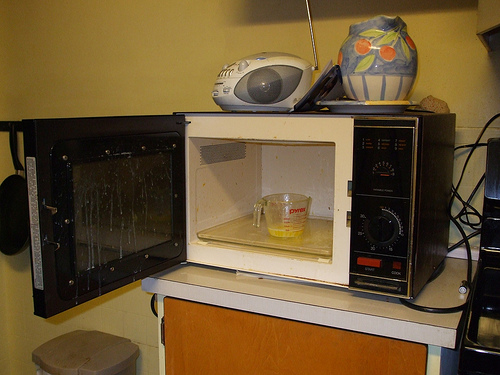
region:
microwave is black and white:
[175, 57, 413, 372]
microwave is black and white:
[57, 55, 359, 332]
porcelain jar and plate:
[336, 17, 422, 116]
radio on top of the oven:
[201, 25, 330, 112]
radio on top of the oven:
[186, 25, 353, 179]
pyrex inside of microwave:
[238, 180, 308, 235]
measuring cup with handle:
[238, 190, 308, 245]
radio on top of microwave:
[211, 45, 311, 107]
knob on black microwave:
[355, 204, 398, 264]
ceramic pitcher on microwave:
[332, 7, 417, 109]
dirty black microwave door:
[21, 117, 195, 307]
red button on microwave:
[345, 256, 383, 271]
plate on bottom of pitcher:
[318, 92, 408, 111]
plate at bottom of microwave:
[196, 220, 322, 253]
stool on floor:
[25, 322, 136, 370]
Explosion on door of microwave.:
[59, 170, 175, 262]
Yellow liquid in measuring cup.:
[259, 206, 325, 270]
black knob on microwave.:
[370, 207, 405, 271]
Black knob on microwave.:
[373, 162, 400, 202]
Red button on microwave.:
[353, 254, 384, 269]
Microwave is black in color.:
[46, 120, 436, 274]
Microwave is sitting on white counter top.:
[189, 224, 391, 324]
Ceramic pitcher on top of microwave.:
[335, 13, 422, 161]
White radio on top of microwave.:
[206, 30, 282, 127]